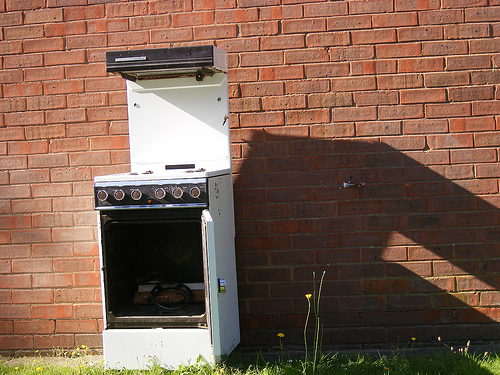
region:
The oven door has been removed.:
[99, 210, 209, 332]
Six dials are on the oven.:
[96, 185, 206, 202]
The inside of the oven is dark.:
[102, 209, 207, 323]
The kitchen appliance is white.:
[93, 48, 243, 371]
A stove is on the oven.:
[95, 168, 231, 178]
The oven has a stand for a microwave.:
[104, 44, 232, 169]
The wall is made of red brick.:
[1, 0, 499, 347]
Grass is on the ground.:
[0, 350, 499, 373]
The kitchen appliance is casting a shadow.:
[233, 128, 498, 353]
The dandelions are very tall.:
[275, 290, 316, 362]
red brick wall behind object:
[238, 48, 388, 105]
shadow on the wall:
[246, 94, 354, 189]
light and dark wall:
[262, 78, 359, 178]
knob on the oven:
[144, 183, 170, 205]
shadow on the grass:
[429, 350, 491, 372]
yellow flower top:
[268, 322, 293, 350]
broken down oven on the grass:
[85, 167, 237, 320]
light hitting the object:
[128, 108, 173, 141]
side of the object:
[210, 181, 240, 351]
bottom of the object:
[88, 329, 223, 369]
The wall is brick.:
[5, 2, 499, 325]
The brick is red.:
[3, 11, 489, 343]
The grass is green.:
[1, 337, 486, 373]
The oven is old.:
[86, 40, 243, 370]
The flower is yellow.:
[303, 290, 313, 301]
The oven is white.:
[82, 45, 250, 374]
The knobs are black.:
[85, 181, 210, 201]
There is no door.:
[97, 205, 220, 332]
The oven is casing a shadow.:
[207, 122, 494, 373]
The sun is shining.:
[3, 6, 496, 373]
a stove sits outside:
[56, 18, 312, 363]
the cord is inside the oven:
[124, 265, 209, 340]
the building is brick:
[271, 78, 441, 157]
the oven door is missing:
[98, 206, 220, 343]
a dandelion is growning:
[271, 320, 296, 365]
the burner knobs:
[88, 188, 218, 206]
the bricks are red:
[306, 153, 457, 278]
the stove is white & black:
[93, 40, 252, 367]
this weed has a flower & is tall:
[296, 266, 354, 371]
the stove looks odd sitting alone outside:
[33, 17, 480, 374]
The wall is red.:
[0, 12, 493, 346]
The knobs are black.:
[86, 175, 223, 220]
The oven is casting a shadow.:
[216, 112, 463, 374]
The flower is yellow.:
[299, 287, 311, 304]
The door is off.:
[86, 207, 227, 324]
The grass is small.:
[1, 341, 496, 370]